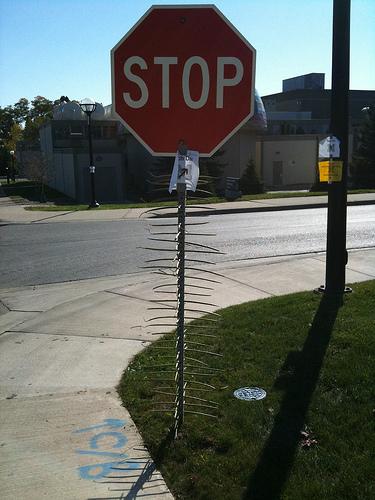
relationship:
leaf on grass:
[283, 417, 319, 429] [217, 393, 323, 489]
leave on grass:
[278, 425, 334, 459] [217, 393, 323, 489]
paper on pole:
[304, 136, 356, 191] [310, 5, 366, 309]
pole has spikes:
[310, 5, 366, 309] [319, 119, 336, 153]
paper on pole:
[304, 136, 356, 191] [171, 147, 192, 434]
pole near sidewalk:
[310, 5, 366, 309] [0, 289, 140, 492]